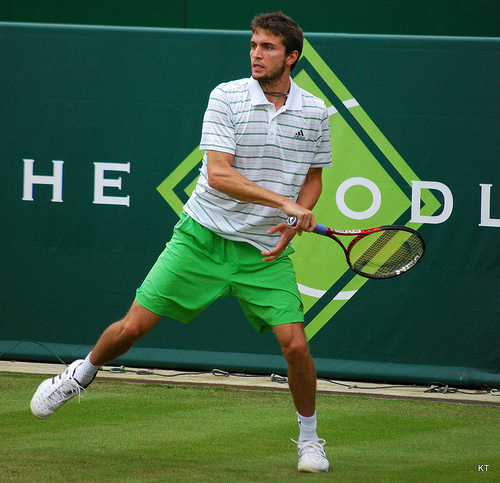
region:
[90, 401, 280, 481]
Ground is green color.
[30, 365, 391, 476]
Shoe is white color.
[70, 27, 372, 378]
One man is playing tennis.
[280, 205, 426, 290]
Player is holding tennis bat.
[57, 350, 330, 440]
Socks are white color.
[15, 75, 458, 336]
Barrier is green color.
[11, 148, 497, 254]
Letters are white color.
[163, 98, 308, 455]
Man is in green and white color.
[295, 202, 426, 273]
Bat is red and black color.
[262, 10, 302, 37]
Hair is brown color.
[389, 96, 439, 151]
part of a banner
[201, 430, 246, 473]
part of a green ground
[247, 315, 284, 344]
edge of a short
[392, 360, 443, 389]
edge of a banner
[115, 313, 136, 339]
part of a knee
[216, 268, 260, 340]
part of a short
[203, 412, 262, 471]
part of a green ground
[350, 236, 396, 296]
edge of a racket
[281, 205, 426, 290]
a red, black and blue tennis racket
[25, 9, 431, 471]
a tennis player swinging a racket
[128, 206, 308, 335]
green men's shorts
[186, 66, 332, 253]
a white and green striped men's shirt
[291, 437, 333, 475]
a white tennis shoe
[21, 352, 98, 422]
a white tennis shoe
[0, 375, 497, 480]
green astroturf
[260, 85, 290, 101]
a corded necklace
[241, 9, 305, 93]
a man's bearded face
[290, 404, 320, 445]
a man's white sock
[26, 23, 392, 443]
this is a tennis player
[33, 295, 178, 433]
the leg is behind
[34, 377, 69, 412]
the shoe is white in color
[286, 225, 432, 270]
this is a racket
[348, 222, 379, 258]
the racket is red in color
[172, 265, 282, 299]
the shorts are green in color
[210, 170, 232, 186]
the hand is folded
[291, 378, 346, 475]
the leg is on the ground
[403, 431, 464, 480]
the pitch is green in color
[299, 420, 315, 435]
the socks is white in color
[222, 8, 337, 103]
man looking at ball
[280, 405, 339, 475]
man with white shoes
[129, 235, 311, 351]
man with green shorts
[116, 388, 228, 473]
green grass under man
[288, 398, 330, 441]
white socks on man's feet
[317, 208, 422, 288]
red and black racket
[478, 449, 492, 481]
letters in bottom right corner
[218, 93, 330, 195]
green and white shirt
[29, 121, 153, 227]
words behind the man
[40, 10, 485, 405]
man playing a game